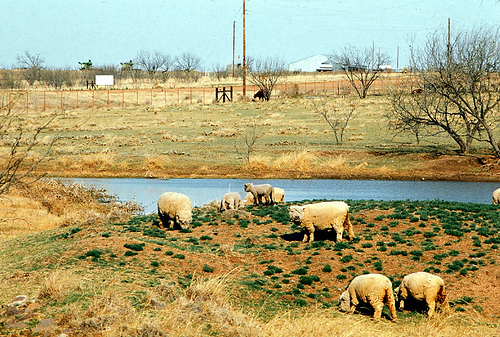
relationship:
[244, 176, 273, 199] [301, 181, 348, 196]
sheep drinking at river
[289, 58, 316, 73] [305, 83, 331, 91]
building by field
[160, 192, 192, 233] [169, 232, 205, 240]
sheep eating grass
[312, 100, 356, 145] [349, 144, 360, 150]
tree without leaf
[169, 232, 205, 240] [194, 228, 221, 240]
grass in dirt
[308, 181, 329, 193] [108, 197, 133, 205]
water in ditch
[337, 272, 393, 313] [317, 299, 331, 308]
sheep eating grass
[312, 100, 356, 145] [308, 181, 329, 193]
tree by water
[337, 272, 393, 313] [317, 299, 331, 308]
sheep eatomg grass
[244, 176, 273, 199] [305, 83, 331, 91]
sheep in field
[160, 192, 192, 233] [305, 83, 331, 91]
sheep in field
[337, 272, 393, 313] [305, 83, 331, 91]
sheep in field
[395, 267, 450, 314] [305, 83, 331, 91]
sheep in field